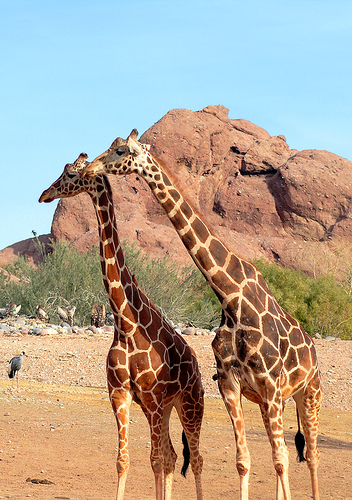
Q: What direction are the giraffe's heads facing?
A: Left.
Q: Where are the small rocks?
A: In front of bushes.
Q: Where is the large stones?
A: Behind the bushes.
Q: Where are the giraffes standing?
A: On brown dirt.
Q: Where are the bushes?
A: Behind the small rocks.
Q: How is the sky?
A: Blue, clear, and sunny.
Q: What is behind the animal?
A: Rocks.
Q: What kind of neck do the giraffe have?
A: Long neck.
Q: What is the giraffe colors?
A: Brown and white.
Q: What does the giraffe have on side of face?
A: Ears.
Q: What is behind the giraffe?
A: Grass.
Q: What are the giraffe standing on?
A: Dirt.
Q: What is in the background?
A: A bird.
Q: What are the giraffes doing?
A: Standing up.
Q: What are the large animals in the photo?
A: Giraffes.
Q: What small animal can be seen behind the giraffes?
A: Bird.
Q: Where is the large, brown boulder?
A: Behind the giraffes.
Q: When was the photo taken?
A: During daylight hours.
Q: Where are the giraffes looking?
A: Toward the bird.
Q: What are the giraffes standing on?
A: Dirt.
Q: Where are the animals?
A: Out of doors.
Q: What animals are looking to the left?
A: Giraffes.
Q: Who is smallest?
A: The bird.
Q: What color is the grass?
A: Green.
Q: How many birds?
A: One.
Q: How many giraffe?
A: Two.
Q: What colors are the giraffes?
A: Brown and cream.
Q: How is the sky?
A: Bright.